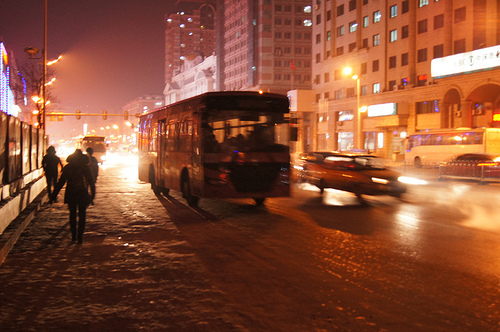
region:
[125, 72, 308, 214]
bus driving down the street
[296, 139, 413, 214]
car heading down the road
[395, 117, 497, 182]
white bus stopped in front of a building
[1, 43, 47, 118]
blue and orange neon lights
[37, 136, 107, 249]
people walking down the street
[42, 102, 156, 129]
traffic signal lights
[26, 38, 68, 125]
several street lights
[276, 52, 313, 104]
red flag on a building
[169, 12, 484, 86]
lots of windows on the buildings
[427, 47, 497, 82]
white rectangular sign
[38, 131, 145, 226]
People walking in the dark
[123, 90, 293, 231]
bus going down the road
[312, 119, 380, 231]
car going down the road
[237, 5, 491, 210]
buildings on the side of the road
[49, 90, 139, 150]
stoplight for traffic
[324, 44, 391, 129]
lit streetlight on the side of the road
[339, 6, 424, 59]
lights on inside the building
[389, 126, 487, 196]
bus stopped in front of building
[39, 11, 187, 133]
dark sky in the night time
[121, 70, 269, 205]
bus travelling down the street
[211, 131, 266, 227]
a bus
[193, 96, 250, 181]
a bus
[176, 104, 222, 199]
a bus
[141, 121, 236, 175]
a bus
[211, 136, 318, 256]
a bus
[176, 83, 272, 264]
a bus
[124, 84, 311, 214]
bus driving on street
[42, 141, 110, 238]
several people walking on the street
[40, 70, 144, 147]
three traffic lights on yellow pole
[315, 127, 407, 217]
vehicle driving past bus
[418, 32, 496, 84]
white sign lit on building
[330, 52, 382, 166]
street light lit on street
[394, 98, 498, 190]
white bus parked on street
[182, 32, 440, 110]
many windows on several buildings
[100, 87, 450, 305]
street is wet from rain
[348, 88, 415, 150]
small white sign over business door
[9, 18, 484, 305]
A city street scene at night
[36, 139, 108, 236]
People are walking along the road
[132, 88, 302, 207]
A bus is travelling on the street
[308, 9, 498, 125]
Buildings are beside the street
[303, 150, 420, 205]
This car is in motion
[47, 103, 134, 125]
Traffic lights are above the street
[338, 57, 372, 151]
A street light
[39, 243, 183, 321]
Snow is on the ground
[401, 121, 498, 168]
A bus is parked here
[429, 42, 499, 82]
This sign is lit up